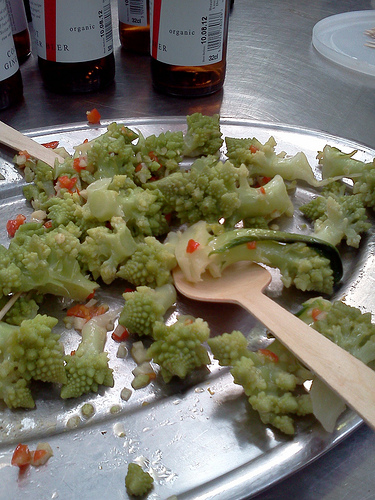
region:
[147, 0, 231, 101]
a bottle of beer is on the table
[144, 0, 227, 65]
the bottle label is white with a red stripe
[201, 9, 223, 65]
a bar code is on the bottle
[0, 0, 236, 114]
six bottles of beer are on the table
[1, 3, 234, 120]
the bottles are brown glass with labels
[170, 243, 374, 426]
a wooden spoon is on the plate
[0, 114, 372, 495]
the round plate is aluminum with a lip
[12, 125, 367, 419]
cooked green broccoflower is on the dish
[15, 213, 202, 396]
the broccoflower is a cultivar of the broccoli family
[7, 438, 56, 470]
pieces of crabmeat are in the dish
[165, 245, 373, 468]
The wooden spoon on the tray.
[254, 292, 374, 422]
The handle of the wooden spoon.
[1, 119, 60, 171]
The wooden handle at the top of the tray.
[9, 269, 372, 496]
The silver tray/pan on the table.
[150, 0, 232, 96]
The brown bottle on the right.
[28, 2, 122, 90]
The brown bottle in the middle.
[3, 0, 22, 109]
The brown bottle on the left.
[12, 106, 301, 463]
The small chopped pieces of tomato.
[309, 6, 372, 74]
The white plastic lid on the right.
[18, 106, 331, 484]
The green vegetable on the tray/pan.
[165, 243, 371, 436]
spoon sitting on silver plate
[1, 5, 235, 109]
brown glass bottles on the table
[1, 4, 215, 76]
white labels on brown bottles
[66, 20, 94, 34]
black lettering on white background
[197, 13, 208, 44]
black numbers on white background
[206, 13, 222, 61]
black barcode on white label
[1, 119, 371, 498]
silver plate sitting on counter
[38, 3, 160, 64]
red stripes on white labels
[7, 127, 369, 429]
light green vegetables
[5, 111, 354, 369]
red specks in light green vegetables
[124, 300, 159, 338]
fibonocci sequence on vegetable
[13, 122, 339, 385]
green and red stir fry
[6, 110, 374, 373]
vegetables on a silver dish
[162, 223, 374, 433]
flat wooden paddle spoon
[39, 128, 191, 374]
green vegetable with red garnish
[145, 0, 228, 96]
brown bottle with white label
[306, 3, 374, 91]
upside down plastic lid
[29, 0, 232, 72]
two white labels marked organic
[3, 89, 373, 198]
silver dish on silver surface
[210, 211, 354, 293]
snow pea on top of a vegetable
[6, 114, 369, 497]
Round silver metal plate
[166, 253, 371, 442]
Wooden spoon on plate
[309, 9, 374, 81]
Round plastic lid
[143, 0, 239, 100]
Brown glass bottle on table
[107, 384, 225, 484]
Moisture drops on plate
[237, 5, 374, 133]
Grey metal table top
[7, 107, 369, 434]
Steamed vegetables on plate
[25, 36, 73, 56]
Bottle label saying ginger beer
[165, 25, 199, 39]
Label with certified organic marking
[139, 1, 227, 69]
Label on bottle of ginger beer